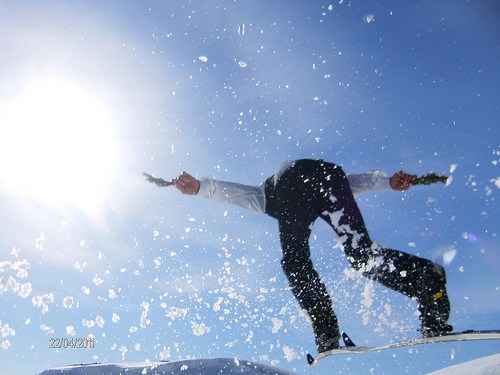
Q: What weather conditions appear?
A: It is clear.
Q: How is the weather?
A: It is clear.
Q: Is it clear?
A: Yes, it is clear.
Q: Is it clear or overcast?
A: It is clear.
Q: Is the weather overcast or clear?
A: It is clear.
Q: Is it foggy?
A: No, it is clear.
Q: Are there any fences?
A: No, there are no fences.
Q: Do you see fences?
A: No, there are no fences.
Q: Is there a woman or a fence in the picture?
A: No, there are no fences or women.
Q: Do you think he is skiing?
A: Yes, the man is skiing.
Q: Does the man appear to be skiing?
A: Yes, the man is skiing.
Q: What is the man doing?
A: The man is skiing.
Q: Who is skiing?
A: The man is skiing.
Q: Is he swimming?
A: No, the man is skiing.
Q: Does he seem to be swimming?
A: No, the man is skiing.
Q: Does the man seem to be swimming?
A: No, the man is skiing.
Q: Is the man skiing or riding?
A: The man is skiing.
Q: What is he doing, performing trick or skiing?
A: The man is skiing.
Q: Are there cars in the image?
A: No, there are no cars.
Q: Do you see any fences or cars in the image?
A: No, there are no cars or fences.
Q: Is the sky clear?
A: Yes, the sky is clear.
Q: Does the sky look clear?
A: Yes, the sky is clear.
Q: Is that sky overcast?
A: No, the sky is clear.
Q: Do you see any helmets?
A: No, there are no helmets.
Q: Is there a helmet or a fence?
A: No, there are no helmets or fences.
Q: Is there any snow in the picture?
A: Yes, there is snow.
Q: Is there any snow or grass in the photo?
A: Yes, there is snow.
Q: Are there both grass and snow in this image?
A: No, there is snow but no grass.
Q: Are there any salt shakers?
A: No, there are no salt shakers.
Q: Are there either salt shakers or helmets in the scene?
A: No, there are no salt shakers or helmets.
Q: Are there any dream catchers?
A: No, there are no dream catchers.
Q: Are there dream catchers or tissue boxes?
A: No, there are no dream catchers or tissue boxes.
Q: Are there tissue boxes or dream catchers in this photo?
A: No, there are no dream catchers or tissue boxes.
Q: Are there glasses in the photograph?
A: No, there are no glasses.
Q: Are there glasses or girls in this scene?
A: No, there are no glasses or girls.